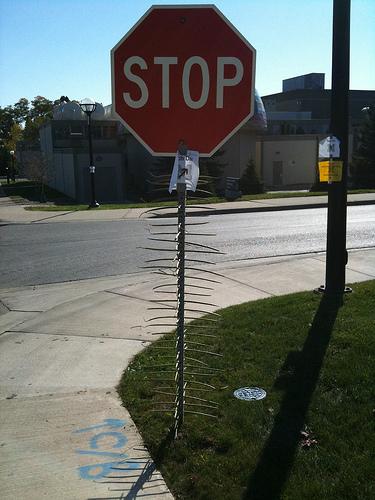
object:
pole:
[177, 147, 186, 433]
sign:
[111, 3, 256, 159]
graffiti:
[71, 417, 139, 480]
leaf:
[301, 430, 318, 446]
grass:
[217, 393, 323, 489]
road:
[0, 193, 375, 283]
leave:
[300, 426, 318, 448]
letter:
[73, 417, 139, 480]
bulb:
[81, 98, 95, 111]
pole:
[324, 0, 352, 294]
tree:
[0, 95, 52, 185]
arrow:
[72, 417, 126, 435]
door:
[273, 160, 282, 185]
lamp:
[78, 97, 100, 208]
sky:
[23, 12, 82, 81]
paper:
[318, 136, 344, 183]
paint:
[72, 417, 139, 485]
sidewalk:
[0, 243, 375, 500]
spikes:
[329, 144, 336, 153]